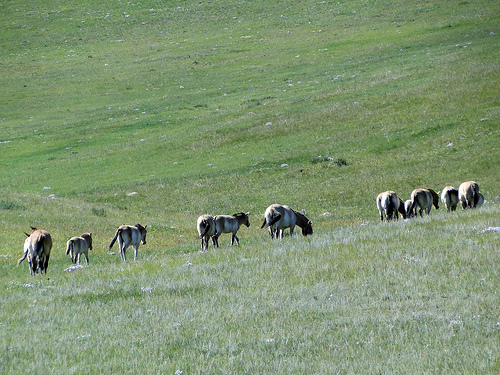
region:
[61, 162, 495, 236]
animal;s are in the field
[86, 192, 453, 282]
the animals are grazing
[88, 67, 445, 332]
the graxzing field is large in size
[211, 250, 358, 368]
the grasse ar short in lenght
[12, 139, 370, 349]
picture taken in the afternooon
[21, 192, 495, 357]
animals are white in color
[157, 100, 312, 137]
the field contains some rocks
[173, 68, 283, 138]
the rocks are gray in color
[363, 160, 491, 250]
animal are walking in one direction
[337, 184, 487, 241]
animals have some brown marks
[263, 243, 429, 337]
a field of grass that is green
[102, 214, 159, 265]
an animal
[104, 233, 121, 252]
the tail of the animal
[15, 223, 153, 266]
animals in the field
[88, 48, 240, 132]
a field of grass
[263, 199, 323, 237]
a horse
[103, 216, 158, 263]
a horse standing in the grass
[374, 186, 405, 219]
the horse is eating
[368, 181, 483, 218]
horses are in the field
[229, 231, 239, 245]
the horses legs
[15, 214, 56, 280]
Large brown and white horse in an open field grazing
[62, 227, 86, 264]
Large brown and white horse in an open field grazing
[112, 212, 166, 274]
Large brown and white horse in an open field grazing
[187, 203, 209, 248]
Large brown and white horse in an open field grazing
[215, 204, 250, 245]
Large brown and white horse in an open field grazing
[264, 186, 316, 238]
Large brown and white horse in an open field grazing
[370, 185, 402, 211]
Large brown and white horse in an open field grazing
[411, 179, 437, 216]
Large brown and white horse in an open field grazing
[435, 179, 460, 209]
Large brown and white horse in an open field grazing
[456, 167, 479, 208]
Large brown and white horse in an open field grazing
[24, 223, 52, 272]
The horse is standing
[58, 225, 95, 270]
The horse is standing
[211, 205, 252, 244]
The horse is standing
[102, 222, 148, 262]
The horse is standing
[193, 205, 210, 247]
The horse is standing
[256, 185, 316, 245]
The horse is standing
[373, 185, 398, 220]
The horse is standing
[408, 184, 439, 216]
The horse is standing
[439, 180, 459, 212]
The horse is standing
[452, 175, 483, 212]
The horse is standing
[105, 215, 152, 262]
horse on the hill.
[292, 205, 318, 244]
horse eating the grass.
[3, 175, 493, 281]
Herd of horses in the forefront.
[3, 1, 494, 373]
Green grass covering the ground.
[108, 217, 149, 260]
white coloring on the horse.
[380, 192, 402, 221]
black tail on the horse.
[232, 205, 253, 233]
Brown head on the horse.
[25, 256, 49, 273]
Legs on the horse.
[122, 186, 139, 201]
Rock in the grass.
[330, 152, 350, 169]
clump of grass on the ground.